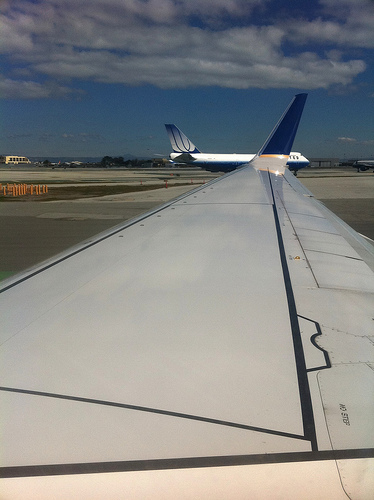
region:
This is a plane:
[147, 111, 343, 187]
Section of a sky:
[0, 69, 95, 117]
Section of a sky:
[68, 29, 162, 92]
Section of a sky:
[151, 47, 235, 103]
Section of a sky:
[250, 37, 338, 80]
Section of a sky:
[78, 9, 172, 59]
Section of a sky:
[9, 15, 84, 81]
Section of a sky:
[112, 2, 223, 60]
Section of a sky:
[224, 10, 306, 66]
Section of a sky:
[275, 16, 346, 49]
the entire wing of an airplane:
[1, 93, 370, 494]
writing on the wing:
[335, 399, 347, 423]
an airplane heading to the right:
[162, 89, 309, 171]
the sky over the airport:
[0, 0, 370, 160]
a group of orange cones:
[0, 177, 47, 193]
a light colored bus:
[0, 151, 27, 160]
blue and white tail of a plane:
[162, 120, 196, 147]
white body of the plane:
[168, 149, 305, 162]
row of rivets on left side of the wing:
[115, 184, 211, 239]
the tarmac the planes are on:
[1, 167, 370, 275]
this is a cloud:
[63, 16, 120, 80]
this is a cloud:
[99, 48, 166, 73]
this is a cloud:
[239, 43, 296, 86]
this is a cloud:
[282, 35, 363, 100]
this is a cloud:
[235, 20, 278, 78]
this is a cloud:
[301, 11, 351, 61]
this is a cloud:
[37, 17, 151, 91]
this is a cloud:
[161, 35, 256, 99]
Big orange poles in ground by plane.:
[4, 172, 55, 201]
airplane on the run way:
[162, 122, 307, 170]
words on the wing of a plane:
[338, 402, 351, 425]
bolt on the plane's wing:
[119, 233, 124, 237]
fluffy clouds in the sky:
[2, 3, 370, 89]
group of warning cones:
[1, 183, 46, 196]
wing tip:
[252, 92, 308, 165]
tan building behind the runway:
[0, 155, 29, 163]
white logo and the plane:
[162, 123, 197, 152]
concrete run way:
[3, 163, 372, 272]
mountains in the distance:
[26, 154, 169, 163]